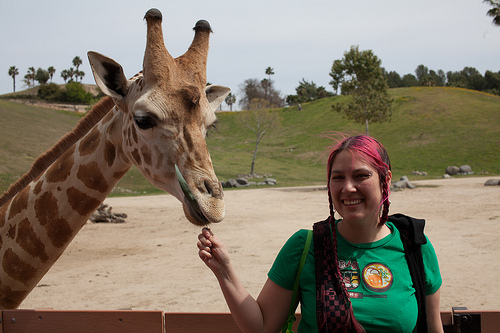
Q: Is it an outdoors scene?
A: Yes, it is outdoors.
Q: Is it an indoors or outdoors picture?
A: It is outdoors.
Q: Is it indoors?
A: No, it is outdoors.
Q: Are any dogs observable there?
A: No, there are no dogs.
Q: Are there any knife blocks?
A: No, there are no knife blocks.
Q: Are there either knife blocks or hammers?
A: No, there are no knife blocks or hammers.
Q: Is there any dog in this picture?
A: No, there are no dogs.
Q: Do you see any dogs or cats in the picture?
A: No, there are no dogs or cats.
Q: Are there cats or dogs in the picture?
A: No, there are no dogs or cats.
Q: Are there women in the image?
A: Yes, there is a woman.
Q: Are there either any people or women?
A: Yes, there is a woman.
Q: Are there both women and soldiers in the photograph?
A: No, there is a woman but no soldiers.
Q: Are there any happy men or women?
A: Yes, there is a happy woman.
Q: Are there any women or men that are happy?
A: Yes, the woman is happy.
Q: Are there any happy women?
A: Yes, there is a happy woman.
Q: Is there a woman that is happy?
A: Yes, there is a woman that is happy.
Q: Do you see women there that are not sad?
A: Yes, there is a happy woman.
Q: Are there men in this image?
A: No, there are no men.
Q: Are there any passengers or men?
A: No, there are no men or passengers.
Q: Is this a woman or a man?
A: This is a woman.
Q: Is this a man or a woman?
A: This is a woman.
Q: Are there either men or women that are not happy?
A: No, there is a woman but she is happy.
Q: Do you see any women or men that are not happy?
A: No, there is a woman but she is happy.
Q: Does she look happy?
A: Yes, the woman is happy.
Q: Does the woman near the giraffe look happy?
A: Yes, the woman is happy.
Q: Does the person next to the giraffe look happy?
A: Yes, the woman is happy.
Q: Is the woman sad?
A: No, the woman is happy.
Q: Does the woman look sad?
A: No, the woman is happy.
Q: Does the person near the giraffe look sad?
A: No, the woman is happy.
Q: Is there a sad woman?
A: No, there is a woman but she is happy.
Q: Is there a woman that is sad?
A: No, there is a woman but she is happy.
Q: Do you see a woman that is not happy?
A: No, there is a woman but she is happy.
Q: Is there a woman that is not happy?
A: No, there is a woman but she is happy.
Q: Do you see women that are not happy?
A: No, there is a woman but she is happy.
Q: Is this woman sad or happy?
A: The woman is happy.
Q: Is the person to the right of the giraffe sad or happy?
A: The woman is happy.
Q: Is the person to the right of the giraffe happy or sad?
A: The woman is happy.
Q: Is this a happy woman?
A: Yes, this is a happy woman.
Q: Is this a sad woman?
A: No, this is a happy woman.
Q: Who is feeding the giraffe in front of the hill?
A: The woman is feeding the giraffe.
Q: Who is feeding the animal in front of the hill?
A: The woman is feeding the giraffe.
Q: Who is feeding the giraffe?
A: The woman is feeding the giraffe.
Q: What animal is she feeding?
A: The woman is feeding the giraffe.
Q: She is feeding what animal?
A: The woman is feeding the giraffe.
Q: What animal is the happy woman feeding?
A: The woman is feeding the giraffe.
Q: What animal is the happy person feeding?
A: The woman is feeding the giraffe.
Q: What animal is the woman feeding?
A: The woman is feeding the giraffe.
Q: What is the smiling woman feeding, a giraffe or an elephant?
A: The woman is feeding a giraffe.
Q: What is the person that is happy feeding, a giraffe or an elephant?
A: The woman is feeding a giraffe.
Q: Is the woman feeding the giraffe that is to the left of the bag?
A: Yes, the woman is feeding the giraffe.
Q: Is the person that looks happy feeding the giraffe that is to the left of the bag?
A: Yes, the woman is feeding the giraffe.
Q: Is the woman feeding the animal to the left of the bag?
A: Yes, the woman is feeding the giraffe.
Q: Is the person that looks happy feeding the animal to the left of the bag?
A: Yes, the woman is feeding the giraffe.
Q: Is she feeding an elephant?
A: No, the woman is feeding the giraffe.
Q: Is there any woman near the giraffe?
A: Yes, there is a woman near the giraffe.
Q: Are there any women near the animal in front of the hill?
A: Yes, there is a woman near the giraffe.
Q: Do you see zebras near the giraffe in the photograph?
A: No, there is a woman near the giraffe.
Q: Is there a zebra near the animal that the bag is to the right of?
A: No, there is a woman near the giraffe.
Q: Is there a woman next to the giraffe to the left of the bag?
A: Yes, there is a woman next to the giraffe.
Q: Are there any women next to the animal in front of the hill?
A: Yes, there is a woman next to the giraffe.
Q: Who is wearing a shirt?
A: The woman is wearing a shirt.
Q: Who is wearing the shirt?
A: The woman is wearing a shirt.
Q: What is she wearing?
A: The woman is wearing a shirt.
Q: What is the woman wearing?
A: The woman is wearing a shirt.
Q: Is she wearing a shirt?
A: Yes, the woman is wearing a shirt.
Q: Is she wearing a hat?
A: No, the woman is wearing a shirt.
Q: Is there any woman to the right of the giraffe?
A: Yes, there is a woman to the right of the giraffe.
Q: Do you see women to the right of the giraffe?
A: Yes, there is a woman to the right of the giraffe.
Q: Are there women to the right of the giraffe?
A: Yes, there is a woman to the right of the giraffe.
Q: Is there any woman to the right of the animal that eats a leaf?
A: Yes, there is a woman to the right of the giraffe.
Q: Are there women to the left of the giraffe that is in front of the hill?
A: No, the woman is to the right of the giraffe.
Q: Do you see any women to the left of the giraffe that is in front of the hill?
A: No, the woman is to the right of the giraffe.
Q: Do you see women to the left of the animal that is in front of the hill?
A: No, the woman is to the right of the giraffe.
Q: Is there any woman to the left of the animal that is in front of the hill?
A: No, the woman is to the right of the giraffe.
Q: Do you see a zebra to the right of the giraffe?
A: No, there is a woman to the right of the giraffe.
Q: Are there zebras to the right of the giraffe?
A: No, there is a woman to the right of the giraffe.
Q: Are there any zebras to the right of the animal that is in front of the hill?
A: No, there is a woman to the right of the giraffe.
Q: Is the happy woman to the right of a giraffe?
A: Yes, the woman is to the right of a giraffe.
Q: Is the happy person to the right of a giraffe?
A: Yes, the woman is to the right of a giraffe.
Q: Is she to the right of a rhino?
A: No, the woman is to the right of a giraffe.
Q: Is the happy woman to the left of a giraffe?
A: No, the woman is to the right of a giraffe.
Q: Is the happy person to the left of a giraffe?
A: No, the woman is to the right of a giraffe.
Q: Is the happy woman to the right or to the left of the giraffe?
A: The woman is to the right of the giraffe.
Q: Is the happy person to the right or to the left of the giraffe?
A: The woman is to the right of the giraffe.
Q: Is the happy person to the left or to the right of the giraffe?
A: The woman is to the right of the giraffe.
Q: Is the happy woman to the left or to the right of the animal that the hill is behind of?
A: The woman is to the right of the giraffe.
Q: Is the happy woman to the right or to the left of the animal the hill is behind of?
A: The woman is to the right of the giraffe.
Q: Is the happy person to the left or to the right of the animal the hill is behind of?
A: The woman is to the right of the giraffe.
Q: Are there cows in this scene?
A: No, there are no cows.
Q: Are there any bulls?
A: No, there are no bulls.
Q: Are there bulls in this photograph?
A: No, there are no bulls.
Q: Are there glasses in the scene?
A: No, there are no glasses.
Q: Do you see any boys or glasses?
A: No, there are no glasses or boys.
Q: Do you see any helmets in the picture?
A: No, there are no helmets.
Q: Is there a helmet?
A: No, there are no helmets.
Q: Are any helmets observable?
A: No, there are no helmets.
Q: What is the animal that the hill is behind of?
A: The animal is a giraffe.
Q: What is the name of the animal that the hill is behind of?
A: The animal is a giraffe.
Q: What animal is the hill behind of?
A: The hill is behind the giraffe.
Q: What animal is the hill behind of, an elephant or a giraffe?
A: The hill is behind a giraffe.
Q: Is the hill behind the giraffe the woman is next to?
A: Yes, the hill is behind the giraffe.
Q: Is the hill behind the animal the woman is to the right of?
A: Yes, the hill is behind the giraffe.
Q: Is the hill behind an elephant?
A: No, the hill is behind the giraffe.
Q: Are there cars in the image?
A: No, there are no cars.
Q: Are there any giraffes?
A: Yes, there is a giraffe.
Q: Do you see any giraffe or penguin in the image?
A: Yes, there is a giraffe.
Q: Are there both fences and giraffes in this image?
A: Yes, there are both a giraffe and a fence.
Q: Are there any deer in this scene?
A: No, there are no deer.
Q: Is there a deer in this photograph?
A: No, there is no deer.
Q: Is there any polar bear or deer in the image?
A: No, there are no deer or polar bears.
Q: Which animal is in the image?
A: The animal is a giraffe.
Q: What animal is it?
A: The animal is a giraffe.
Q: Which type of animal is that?
A: This is a giraffe.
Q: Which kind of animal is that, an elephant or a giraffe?
A: This is a giraffe.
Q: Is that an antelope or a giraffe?
A: That is a giraffe.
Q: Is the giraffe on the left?
A: Yes, the giraffe is on the left of the image.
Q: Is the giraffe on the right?
A: No, the giraffe is on the left of the image.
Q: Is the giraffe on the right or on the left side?
A: The giraffe is on the left of the image.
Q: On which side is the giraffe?
A: The giraffe is on the left of the image.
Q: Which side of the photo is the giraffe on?
A: The giraffe is on the left of the image.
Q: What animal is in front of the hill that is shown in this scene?
A: The giraffe is in front of the hill.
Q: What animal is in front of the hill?
A: The giraffe is in front of the hill.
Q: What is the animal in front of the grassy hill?
A: The animal is a giraffe.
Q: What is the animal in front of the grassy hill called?
A: The animal is a giraffe.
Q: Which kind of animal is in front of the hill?
A: The animal is a giraffe.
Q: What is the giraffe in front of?
A: The giraffe is in front of the hill.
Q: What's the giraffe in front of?
A: The giraffe is in front of the hill.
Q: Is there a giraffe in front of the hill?
A: Yes, there is a giraffe in front of the hill.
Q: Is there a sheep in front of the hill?
A: No, there is a giraffe in front of the hill.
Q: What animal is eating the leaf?
A: The giraffe is eating the leaf.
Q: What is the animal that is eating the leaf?
A: The animal is a giraffe.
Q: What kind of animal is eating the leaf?
A: The animal is a giraffe.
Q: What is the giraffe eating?
A: The giraffe is eating a leaf.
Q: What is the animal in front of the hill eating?
A: The giraffe is eating a leaf.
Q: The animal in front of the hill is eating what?
A: The giraffe is eating a leaf.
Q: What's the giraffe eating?
A: The giraffe is eating a leaf.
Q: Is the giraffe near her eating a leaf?
A: Yes, the giraffe is eating a leaf.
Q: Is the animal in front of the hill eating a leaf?
A: Yes, the giraffe is eating a leaf.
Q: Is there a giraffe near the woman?
A: Yes, there is a giraffe near the woman.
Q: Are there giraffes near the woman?
A: Yes, there is a giraffe near the woman.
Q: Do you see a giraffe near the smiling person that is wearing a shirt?
A: Yes, there is a giraffe near the woman.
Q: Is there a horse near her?
A: No, there is a giraffe near the woman.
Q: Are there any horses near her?
A: No, there is a giraffe near the woman.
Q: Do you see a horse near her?
A: No, there is a giraffe near the woman.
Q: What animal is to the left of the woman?
A: The animal is a giraffe.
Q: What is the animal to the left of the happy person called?
A: The animal is a giraffe.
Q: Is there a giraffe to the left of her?
A: Yes, there is a giraffe to the left of the woman.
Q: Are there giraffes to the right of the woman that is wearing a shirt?
A: No, the giraffe is to the left of the woman.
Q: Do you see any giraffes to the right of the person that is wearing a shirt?
A: No, the giraffe is to the left of the woman.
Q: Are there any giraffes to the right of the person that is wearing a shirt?
A: No, the giraffe is to the left of the woman.